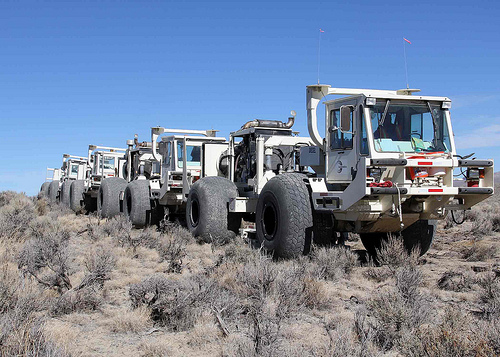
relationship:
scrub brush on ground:
[14, 240, 69, 282] [9, 192, 483, 347]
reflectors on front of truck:
[416, 158, 443, 193] [184, 77, 495, 261]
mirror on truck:
[329, 111, 361, 152] [260, 77, 482, 285]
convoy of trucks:
[68, 53, 481, 297] [40, 84, 495, 266]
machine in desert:
[185, 82, 496, 262] [6, 259, 495, 348]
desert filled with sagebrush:
[0, 188, 499, 355] [0, 188, 499, 355]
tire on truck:
[251, 168, 318, 260] [184, 77, 495, 261]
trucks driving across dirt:
[40, 84, 495, 266] [11, 191, 476, 334]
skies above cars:
[3, 1, 489, 77] [40, 90, 468, 268]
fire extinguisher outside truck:
[463, 163, 487, 188] [184, 77, 495, 261]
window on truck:
[363, 98, 454, 155] [241, 84, 428, 244]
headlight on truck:
[362, 94, 377, 107] [259, 111, 448, 255]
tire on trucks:
[255, 172, 315, 260] [25, 71, 485, 260]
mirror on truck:
[328, 105, 354, 135] [221, 94, 475, 236]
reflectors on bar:
[416, 158, 443, 193] [385, 152, 458, 182]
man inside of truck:
[373, 109, 410, 142] [226, 70, 498, 222]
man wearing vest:
[374, 112, 403, 140] [380, 111, 450, 157]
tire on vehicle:
[255, 172, 315, 260] [251, 85, 497, 273]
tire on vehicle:
[255, 172, 315, 260] [183, 81, 491, 267]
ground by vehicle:
[0, 170, 497, 355] [183, 81, 491, 267]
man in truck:
[374, 112, 403, 140] [180, 23, 497, 258]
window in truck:
[353, 94, 465, 162] [267, 110, 434, 250]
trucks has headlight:
[48, 84, 499, 294] [358, 180, 396, 192]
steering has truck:
[398, 126, 430, 146] [255, 89, 465, 264]